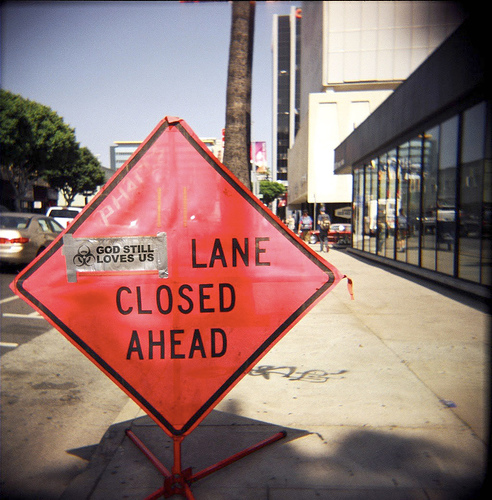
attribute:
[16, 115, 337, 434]
sign —  orange,  warning , for construction 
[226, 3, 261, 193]
trunk —  tree's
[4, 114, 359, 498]
sign —  orange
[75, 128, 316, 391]
sign —  lane closed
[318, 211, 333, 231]
backpack — beige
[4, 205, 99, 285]
car —   tan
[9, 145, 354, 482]
warning — road warning, red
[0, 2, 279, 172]
sky — blue, clear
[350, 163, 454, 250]
windows —  large,  several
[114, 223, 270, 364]
lettering —  black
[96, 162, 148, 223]
graffiti —  black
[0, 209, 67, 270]
car —  gold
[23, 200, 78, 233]
truck — pick up, white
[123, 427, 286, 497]
base —  orange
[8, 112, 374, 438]
sign —  for construction,  orange,  triangle shaped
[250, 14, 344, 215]
tall building —  with several levels,  tall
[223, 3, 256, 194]
tree —  tall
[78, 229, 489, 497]
sidewalk —  concrete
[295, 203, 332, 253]
people —  two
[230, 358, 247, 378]
border —  black 